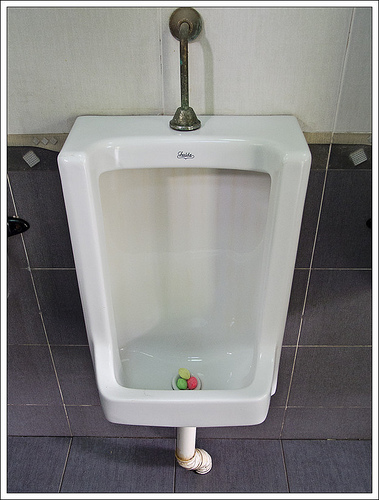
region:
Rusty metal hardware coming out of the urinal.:
[167, 7, 202, 131]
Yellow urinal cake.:
[176, 367, 190, 380]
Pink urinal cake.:
[187, 376, 198, 390]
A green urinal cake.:
[176, 377, 186, 389]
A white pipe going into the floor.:
[176, 426, 211, 473]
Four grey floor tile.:
[8, 435, 371, 491]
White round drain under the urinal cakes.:
[171, 371, 200, 389]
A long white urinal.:
[55, 114, 311, 428]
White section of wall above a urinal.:
[6, 8, 372, 135]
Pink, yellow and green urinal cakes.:
[175, 366, 197, 390]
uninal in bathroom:
[55, 114, 313, 428]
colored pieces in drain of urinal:
[175, 366, 197, 390]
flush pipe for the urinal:
[166, 6, 203, 131]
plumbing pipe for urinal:
[172, 426, 213, 474]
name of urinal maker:
[174, 150, 194, 161]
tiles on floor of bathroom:
[7, 436, 371, 493]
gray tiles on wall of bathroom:
[0, 144, 369, 436]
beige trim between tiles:
[9, 132, 373, 152]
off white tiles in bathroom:
[9, 7, 371, 134]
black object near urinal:
[7, 215, 30, 237]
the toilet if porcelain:
[53, 101, 313, 485]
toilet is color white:
[47, 91, 316, 475]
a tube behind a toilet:
[170, 420, 217, 478]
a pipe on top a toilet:
[161, 9, 217, 133]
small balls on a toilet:
[164, 362, 204, 396]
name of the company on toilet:
[155, 141, 209, 170]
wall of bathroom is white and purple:
[13, 10, 371, 445]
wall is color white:
[8, 14, 370, 127]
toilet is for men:
[43, 105, 327, 441]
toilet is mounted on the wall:
[53, 101, 318, 447]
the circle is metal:
[168, 6, 201, 39]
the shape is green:
[177, 378, 186, 388]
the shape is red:
[188, 376, 195, 386]